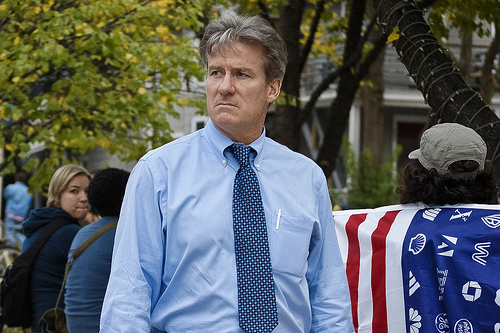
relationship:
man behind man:
[393, 123, 500, 208] [98, 10, 354, 331]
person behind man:
[62, 166, 129, 331] [98, 10, 354, 331]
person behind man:
[13, 163, 94, 333] [98, 10, 354, 331]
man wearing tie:
[98, 10, 355, 333] [220, 144, 280, 331]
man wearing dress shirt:
[98, 10, 355, 333] [97, 114, 360, 333]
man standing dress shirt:
[98, 10, 355, 333] [97, 114, 360, 333]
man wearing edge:
[98, 10, 354, 331] [230, 171, 245, 331]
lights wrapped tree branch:
[376, 5, 487, 133] [375, 6, 486, 152]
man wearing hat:
[393, 123, 500, 208] [412, 115, 488, 188]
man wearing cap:
[393, 123, 500, 208] [408, 121, 485, 179]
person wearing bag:
[13, 163, 94, 333] [0, 208, 100, 330]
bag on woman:
[14, 187, 114, 311] [21, 131, 99, 330]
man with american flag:
[393, 123, 500, 208] [325, 200, 500, 332]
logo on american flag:
[406, 235, 426, 250] [325, 200, 500, 332]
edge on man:
[230, 171, 245, 331] [98, 10, 354, 331]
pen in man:
[272, 209, 284, 230] [144, 31, 326, 319]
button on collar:
[254, 162, 259, 170] [206, 121, 267, 171]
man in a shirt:
[98, 10, 354, 331] [117, 112, 370, 332]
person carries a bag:
[62, 166, 129, 331] [40, 219, 119, 333]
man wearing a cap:
[385, 116, 496, 237] [408, 123, 485, 181]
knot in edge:
[227, 142, 253, 181] [230, 171, 245, 331]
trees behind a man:
[5, 16, 202, 150] [98, 10, 354, 331]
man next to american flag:
[98, 10, 355, 333] [325, 200, 500, 332]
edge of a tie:
[230, 171, 245, 331] [228, 217, 266, 290]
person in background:
[62, 166, 128, 333] [5, 122, 499, 333]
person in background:
[13, 163, 94, 331] [5, 122, 499, 333]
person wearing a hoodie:
[13, 163, 94, 333] [18, 204, 81, 331]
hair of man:
[199, 12, 286, 73] [98, 10, 354, 331]